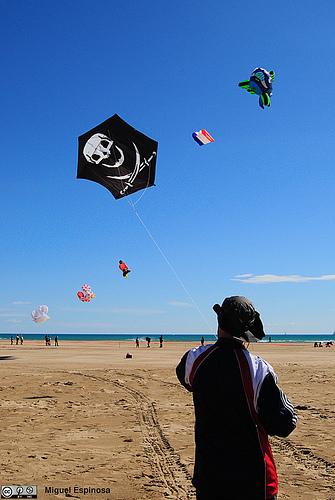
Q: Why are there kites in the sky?
A: It is windy.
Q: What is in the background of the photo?
A: Blue skies and people.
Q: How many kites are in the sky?
A: Six.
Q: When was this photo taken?
A: Daytime.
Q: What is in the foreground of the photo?
A: A pirate flying a kite.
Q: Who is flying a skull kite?
A: A pirate.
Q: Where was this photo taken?
A: On the beach.